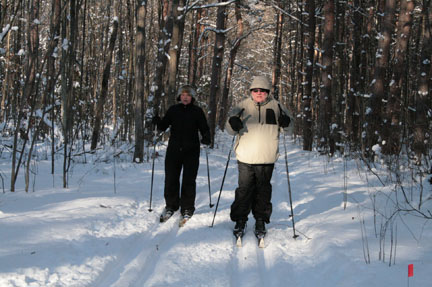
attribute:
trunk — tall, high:
[132, 35, 146, 163]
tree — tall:
[317, 12, 338, 161]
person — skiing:
[231, 70, 292, 238]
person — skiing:
[144, 73, 212, 224]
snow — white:
[2, 129, 431, 285]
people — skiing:
[151, 70, 294, 238]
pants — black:
[158, 145, 206, 218]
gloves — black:
[227, 111, 295, 133]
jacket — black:
[151, 100, 210, 149]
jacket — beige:
[233, 72, 284, 165]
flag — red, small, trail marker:
[395, 258, 425, 286]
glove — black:
[198, 127, 216, 151]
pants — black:
[229, 163, 274, 231]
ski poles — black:
[203, 132, 238, 226]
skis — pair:
[219, 234, 272, 250]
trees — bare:
[1, 2, 432, 158]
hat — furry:
[172, 80, 201, 108]